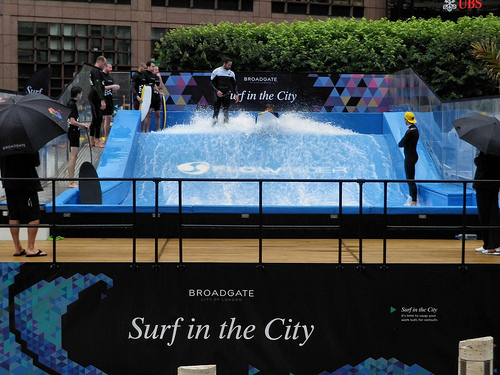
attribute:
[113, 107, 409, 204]
water — blue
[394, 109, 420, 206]
person — standing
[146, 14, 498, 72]
bush — green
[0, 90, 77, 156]
umbrella — black, open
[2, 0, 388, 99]
building — brown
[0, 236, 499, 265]
floor — brow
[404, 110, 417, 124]
cap — yellow, backwards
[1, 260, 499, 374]
banner — black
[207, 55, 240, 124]
person — standing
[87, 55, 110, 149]
person — standing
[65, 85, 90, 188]
person — standing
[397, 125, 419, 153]
top — black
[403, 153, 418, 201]
pants — black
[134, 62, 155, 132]
person — standing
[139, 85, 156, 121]
object — white, yellow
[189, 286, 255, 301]
word — white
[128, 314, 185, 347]
word — white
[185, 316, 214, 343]
word — white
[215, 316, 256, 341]
word — white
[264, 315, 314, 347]
word — white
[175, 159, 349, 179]
logo — white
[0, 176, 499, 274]
rail — black